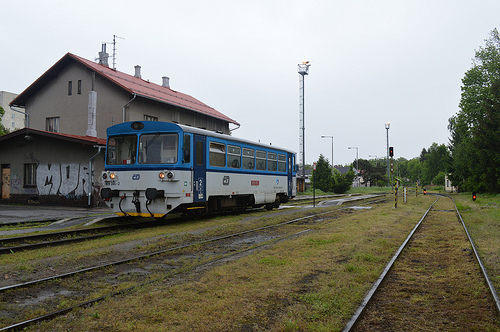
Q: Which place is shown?
A: It is a station.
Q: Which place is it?
A: It is a station.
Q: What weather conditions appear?
A: It is overcast.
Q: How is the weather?
A: It is overcast.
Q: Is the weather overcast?
A: Yes, it is overcast.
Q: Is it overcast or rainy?
A: It is overcast.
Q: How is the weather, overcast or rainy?
A: It is overcast.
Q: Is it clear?
A: No, it is overcast.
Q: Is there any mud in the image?
A: Yes, there is mud.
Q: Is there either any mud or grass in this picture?
A: Yes, there is mud.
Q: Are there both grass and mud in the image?
A: Yes, there are both mud and grass.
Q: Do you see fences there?
A: No, there are no fences.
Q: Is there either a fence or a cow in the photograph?
A: No, there are no fences or cows.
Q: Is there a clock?
A: No, there are no clocks.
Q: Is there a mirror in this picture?
A: No, there are no mirrors.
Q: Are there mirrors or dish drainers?
A: No, there are no mirrors or dish drainers.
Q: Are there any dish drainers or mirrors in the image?
A: No, there are no mirrors or dish drainers.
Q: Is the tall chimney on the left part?
A: Yes, the chimney is on the left of the image.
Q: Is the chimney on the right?
A: No, the chimney is on the left of the image.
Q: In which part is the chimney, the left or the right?
A: The chimney is on the left of the image.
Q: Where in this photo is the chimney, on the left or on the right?
A: The chimney is on the left of the image.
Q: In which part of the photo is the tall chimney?
A: The chimney is on the left of the image.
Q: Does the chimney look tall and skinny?
A: Yes, the chimney is tall and skinny.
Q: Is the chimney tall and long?
A: Yes, the chimney is tall and long.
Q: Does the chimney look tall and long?
A: Yes, the chimney is tall and long.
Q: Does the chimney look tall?
A: Yes, the chimney is tall.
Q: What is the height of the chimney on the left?
A: The chimney is tall.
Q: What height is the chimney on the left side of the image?
A: The chimney is tall.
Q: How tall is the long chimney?
A: The chimney is tall.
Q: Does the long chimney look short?
A: No, the chimney is tall.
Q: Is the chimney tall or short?
A: The chimney is tall.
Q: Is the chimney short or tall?
A: The chimney is tall.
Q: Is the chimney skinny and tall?
A: Yes, the chimney is skinny and tall.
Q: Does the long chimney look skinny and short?
A: No, the chimney is skinny but tall.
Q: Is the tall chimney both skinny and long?
A: Yes, the chimney is skinny and long.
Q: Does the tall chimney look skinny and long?
A: Yes, the chimney is skinny and long.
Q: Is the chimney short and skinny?
A: No, the chimney is skinny but long.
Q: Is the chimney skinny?
A: Yes, the chimney is skinny.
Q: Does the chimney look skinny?
A: Yes, the chimney is skinny.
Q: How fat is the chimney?
A: The chimney is skinny.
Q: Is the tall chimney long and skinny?
A: Yes, the chimney is long and skinny.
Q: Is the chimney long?
A: Yes, the chimney is long.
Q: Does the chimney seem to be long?
A: Yes, the chimney is long.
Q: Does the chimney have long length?
A: Yes, the chimney is long.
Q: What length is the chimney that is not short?
A: The chimney is long.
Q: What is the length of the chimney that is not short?
A: The chimney is long.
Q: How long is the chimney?
A: The chimney is long.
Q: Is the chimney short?
A: No, the chimney is long.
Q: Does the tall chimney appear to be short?
A: No, the chimney is long.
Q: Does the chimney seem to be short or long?
A: The chimney is long.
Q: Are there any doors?
A: Yes, there is a door.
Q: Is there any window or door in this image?
A: Yes, there is a door.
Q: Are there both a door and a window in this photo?
A: Yes, there are both a door and a window.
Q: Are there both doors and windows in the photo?
A: Yes, there are both a door and a window.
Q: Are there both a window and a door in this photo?
A: Yes, there are both a door and a window.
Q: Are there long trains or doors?
A: Yes, there is a long door.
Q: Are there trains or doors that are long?
A: Yes, the door is long.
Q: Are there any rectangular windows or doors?
A: Yes, there is a rectangular door.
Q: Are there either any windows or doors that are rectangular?
A: Yes, the door is rectangular.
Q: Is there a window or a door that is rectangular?
A: Yes, the door is rectangular.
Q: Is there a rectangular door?
A: Yes, there is a rectangular door.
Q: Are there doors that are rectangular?
A: Yes, there is a door that is rectangular.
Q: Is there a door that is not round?
A: Yes, there is a rectangular door.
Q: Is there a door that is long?
A: Yes, there is a long door.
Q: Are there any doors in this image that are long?
A: Yes, there is a door that is long.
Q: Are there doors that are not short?
A: Yes, there is a long door.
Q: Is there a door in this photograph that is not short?
A: Yes, there is a long door.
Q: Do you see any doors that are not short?
A: Yes, there is a long door.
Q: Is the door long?
A: Yes, the door is long.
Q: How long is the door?
A: The door is long.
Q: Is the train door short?
A: No, the door is long.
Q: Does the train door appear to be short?
A: No, the door is long.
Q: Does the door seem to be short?
A: No, the door is long.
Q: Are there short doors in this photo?
A: No, there is a door but it is long.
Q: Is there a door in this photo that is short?
A: No, there is a door but it is long.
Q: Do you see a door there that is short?
A: No, there is a door but it is long.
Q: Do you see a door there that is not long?
A: No, there is a door but it is long.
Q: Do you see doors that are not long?
A: No, there is a door but it is long.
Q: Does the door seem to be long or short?
A: The door is long.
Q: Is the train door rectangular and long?
A: Yes, the door is rectangular and long.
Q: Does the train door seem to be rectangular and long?
A: Yes, the door is rectangular and long.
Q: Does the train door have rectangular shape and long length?
A: Yes, the door is rectangular and long.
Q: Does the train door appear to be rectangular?
A: Yes, the door is rectangular.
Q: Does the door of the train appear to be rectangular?
A: Yes, the door is rectangular.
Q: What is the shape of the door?
A: The door is rectangular.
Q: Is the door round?
A: No, the door is rectangular.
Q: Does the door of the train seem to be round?
A: No, the door is rectangular.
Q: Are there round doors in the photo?
A: No, there is a door but it is rectangular.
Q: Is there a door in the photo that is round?
A: No, there is a door but it is rectangular.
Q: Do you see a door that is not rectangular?
A: No, there is a door but it is rectangular.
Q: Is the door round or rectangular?
A: The door is rectangular.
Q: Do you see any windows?
A: Yes, there is a window.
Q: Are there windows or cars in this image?
A: Yes, there is a window.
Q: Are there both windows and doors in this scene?
A: Yes, there are both a window and a door.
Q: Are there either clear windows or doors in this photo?
A: Yes, there is a clear window.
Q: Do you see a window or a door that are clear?
A: Yes, the window is clear.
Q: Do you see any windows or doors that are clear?
A: Yes, the window is clear.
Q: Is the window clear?
A: Yes, the window is clear.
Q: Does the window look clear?
A: Yes, the window is clear.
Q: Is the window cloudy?
A: No, the window is clear.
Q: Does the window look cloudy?
A: No, the window is clear.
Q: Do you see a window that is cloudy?
A: No, there is a window but it is clear.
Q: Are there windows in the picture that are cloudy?
A: No, there is a window but it is clear.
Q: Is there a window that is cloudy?
A: No, there is a window but it is clear.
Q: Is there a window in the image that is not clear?
A: No, there is a window but it is clear.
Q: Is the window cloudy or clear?
A: The window is clear.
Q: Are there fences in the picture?
A: No, there are no fences.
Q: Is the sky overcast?
A: Yes, the sky is overcast.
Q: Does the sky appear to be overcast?
A: Yes, the sky is overcast.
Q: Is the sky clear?
A: No, the sky is overcast.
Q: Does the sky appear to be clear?
A: No, the sky is overcast.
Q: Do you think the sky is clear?
A: No, the sky is overcast.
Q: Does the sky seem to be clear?
A: No, the sky is overcast.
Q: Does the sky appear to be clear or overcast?
A: The sky is overcast.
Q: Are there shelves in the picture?
A: No, there are no shelves.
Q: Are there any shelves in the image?
A: No, there are no shelves.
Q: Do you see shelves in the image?
A: No, there are no shelves.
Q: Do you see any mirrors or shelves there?
A: No, there are no shelves or mirrors.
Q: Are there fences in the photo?
A: No, there are no fences.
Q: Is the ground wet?
A: Yes, the ground is wet.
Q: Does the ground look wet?
A: Yes, the ground is wet.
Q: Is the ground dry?
A: No, the ground is wet.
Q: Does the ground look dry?
A: No, the ground is wet.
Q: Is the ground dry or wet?
A: The ground is wet.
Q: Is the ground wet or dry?
A: The ground is wet.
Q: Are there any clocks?
A: No, there are no clocks.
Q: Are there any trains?
A: Yes, there is a train.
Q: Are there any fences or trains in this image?
A: Yes, there is a train.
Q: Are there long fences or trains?
A: Yes, there is a long train.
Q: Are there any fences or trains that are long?
A: Yes, the train is long.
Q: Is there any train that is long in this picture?
A: Yes, there is a long train.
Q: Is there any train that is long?
A: Yes, there is a train that is long.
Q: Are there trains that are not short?
A: Yes, there is a long train.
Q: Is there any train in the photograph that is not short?
A: Yes, there is a long train.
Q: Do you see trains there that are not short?
A: Yes, there is a long train.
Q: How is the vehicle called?
A: The vehicle is a train.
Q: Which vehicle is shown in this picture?
A: The vehicle is a train.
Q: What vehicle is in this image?
A: The vehicle is a train.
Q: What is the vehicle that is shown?
A: The vehicle is a train.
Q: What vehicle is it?
A: The vehicle is a train.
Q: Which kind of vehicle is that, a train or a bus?
A: That is a train.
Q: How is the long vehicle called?
A: The vehicle is a train.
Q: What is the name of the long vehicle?
A: The vehicle is a train.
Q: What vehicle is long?
A: The vehicle is a train.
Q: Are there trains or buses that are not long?
A: No, there is a train but it is long.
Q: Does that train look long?
A: Yes, the train is long.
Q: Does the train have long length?
A: Yes, the train is long.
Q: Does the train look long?
A: Yes, the train is long.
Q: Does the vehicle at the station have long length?
A: Yes, the train is long.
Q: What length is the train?
A: The train is long.